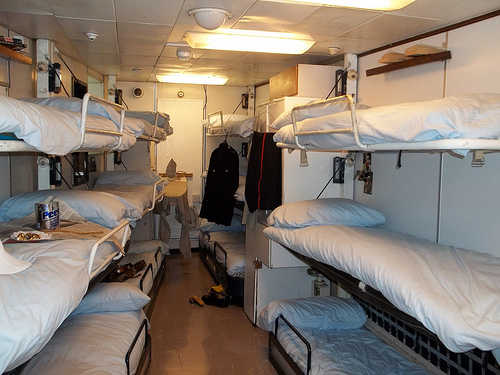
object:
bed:
[270, 92, 499, 159]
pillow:
[28, 96, 98, 113]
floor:
[137, 247, 272, 374]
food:
[10, 228, 53, 244]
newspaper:
[0, 194, 124, 255]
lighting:
[181, 32, 318, 57]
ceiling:
[45, 0, 493, 89]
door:
[155, 100, 203, 240]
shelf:
[363, 51, 449, 78]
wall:
[343, 23, 498, 107]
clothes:
[196, 139, 240, 226]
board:
[0, 136, 118, 159]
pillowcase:
[266, 96, 374, 128]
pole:
[339, 55, 359, 106]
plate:
[11, 228, 50, 242]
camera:
[39, 58, 62, 71]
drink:
[33, 202, 62, 232]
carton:
[36, 201, 64, 233]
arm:
[291, 95, 358, 124]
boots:
[186, 291, 204, 308]